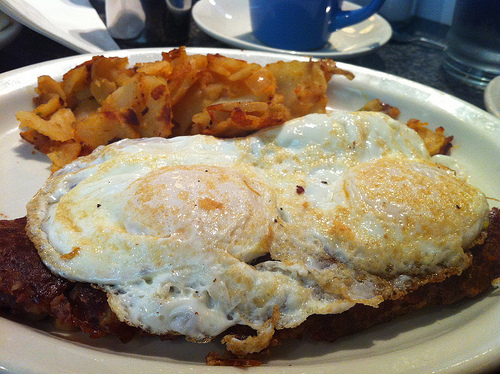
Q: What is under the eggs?
A: Meat.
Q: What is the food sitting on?
A: A plate.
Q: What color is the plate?
A: White.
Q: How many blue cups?
A: One.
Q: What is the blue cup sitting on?
A: A saucer.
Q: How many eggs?
A: Two.